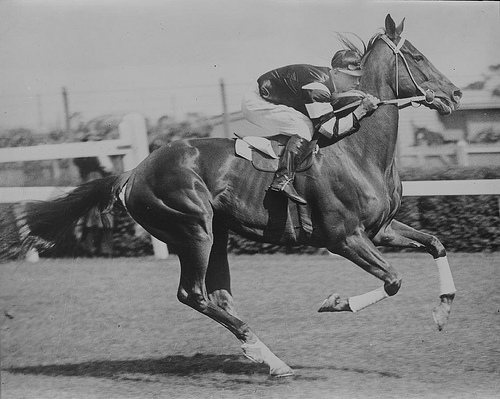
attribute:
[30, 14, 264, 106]
clouds — white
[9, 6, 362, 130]
sky — blue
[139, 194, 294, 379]
legs — powerful, back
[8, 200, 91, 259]
hair — long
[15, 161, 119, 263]
tail — horse's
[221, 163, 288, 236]
cage — rib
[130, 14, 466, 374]
horse — brown, running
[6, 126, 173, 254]
fence — white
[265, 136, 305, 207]
boot — leather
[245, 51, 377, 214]
man — small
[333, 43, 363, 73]
cap — dark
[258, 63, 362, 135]
shirt — dark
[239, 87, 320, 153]
pants — white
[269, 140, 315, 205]
boots — dark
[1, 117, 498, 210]
fence — white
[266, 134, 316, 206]
boot — black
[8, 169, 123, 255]
tail — long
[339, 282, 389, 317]
ankles — taped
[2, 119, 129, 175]
railing — white